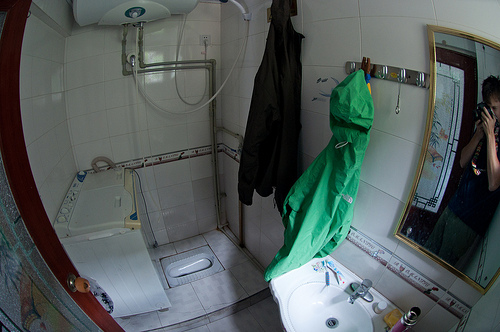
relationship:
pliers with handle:
[342, 39, 393, 109] [362, 73, 373, 99]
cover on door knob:
[74, 277, 91, 297] [66, 272, 92, 294]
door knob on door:
[66, 272, 92, 294] [2, 1, 131, 330]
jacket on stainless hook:
[263, 67, 375, 283] [339, 60, 429, 95]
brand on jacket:
[345, 195, 353, 205] [266, 70, 374, 277]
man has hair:
[443, 90, 499, 275] [469, 77, 499, 100]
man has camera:
[443, 90, 499, 275] [469, 98, 498, 123]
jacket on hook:
[272, 62, 372, 276] [357, 52, 374, 82]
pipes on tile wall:
[117, 19, 277, 288] [57, 0, 229, 254]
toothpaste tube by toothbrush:
[324, 260, 348, 288] [318, 270, 335, 288]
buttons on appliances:
[54, 200, 79, 228] [53, 152, 190, 320]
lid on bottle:
[400, 303, 420, 325] [388, 305, 415, 330]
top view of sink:
[153, 167, 395, 329] [206, 200, 391, 327]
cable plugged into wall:
[77, 33, 336, 113] [114, 11, 310, 137]